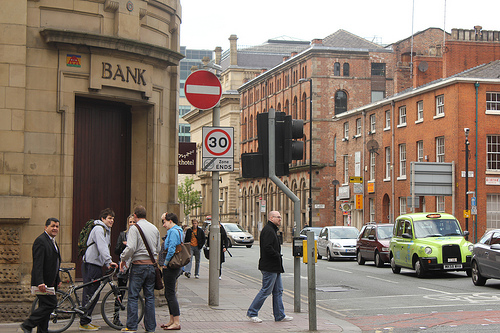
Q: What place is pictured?
A: It is a street.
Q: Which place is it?
A: It is a street.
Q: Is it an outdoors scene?
A: Yes, it is outdoors.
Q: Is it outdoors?
A: Yes, it is outdoors.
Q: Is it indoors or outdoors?
A: It is outdoors.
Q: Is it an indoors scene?
A: No, it is outdoors.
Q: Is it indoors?
A: No, it is outdoors.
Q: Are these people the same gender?
A: No, they are both male and female.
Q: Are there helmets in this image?
A: No, there are no helmets.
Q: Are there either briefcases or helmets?
A: No, there are no helmets or briefcases.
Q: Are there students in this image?
A: No, there are no students.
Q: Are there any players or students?
A: No, there are no students or players.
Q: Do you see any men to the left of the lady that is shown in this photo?
A: Yes, there is a man to the left of the lady.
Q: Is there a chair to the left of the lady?
A: No, there is a man to the left of the lady.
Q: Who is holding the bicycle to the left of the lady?
A: The man is holding the bicycle.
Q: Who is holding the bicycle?
A: The man is holding the bicycle.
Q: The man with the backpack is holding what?
A: The man is holding the bicycle.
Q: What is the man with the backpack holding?
A: The man is holding the bicycle.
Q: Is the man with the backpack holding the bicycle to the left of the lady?
A: Yes, the man is holding the bicycle.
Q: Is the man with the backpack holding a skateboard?
A: No, the man is holding the bicycle.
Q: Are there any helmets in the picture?
A: No, there are no helmets.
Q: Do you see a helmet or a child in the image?
A: No, there are no helmets or children.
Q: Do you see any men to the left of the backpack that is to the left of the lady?
A: Yes, there is a man to the left of the backpack.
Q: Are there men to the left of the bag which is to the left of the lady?
A: Yes, there is a man to the left of the backpack.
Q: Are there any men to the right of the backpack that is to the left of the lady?
A: No, the man is to the left of the backpack.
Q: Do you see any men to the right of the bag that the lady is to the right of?
A: No, the man is to the left of the backpack.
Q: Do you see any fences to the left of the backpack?
A: No, there is a man to the left of the backpack.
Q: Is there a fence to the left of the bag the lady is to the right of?
A: No, there is a man to the left of the backpack.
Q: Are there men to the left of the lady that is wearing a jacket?
A: Yes, there is a man to the left of the lady.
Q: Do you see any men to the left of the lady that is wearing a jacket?
A: Yes, there is a man to the left of the lady.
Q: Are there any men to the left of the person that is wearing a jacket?
A: Yes, there is a man to the left of the lady.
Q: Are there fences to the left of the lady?
A: No, there is a man to the left of the lady.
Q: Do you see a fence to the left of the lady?
A: No, there is a man to the left of the lady.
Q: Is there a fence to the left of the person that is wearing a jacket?
A: No, there is a man to the left of the lady.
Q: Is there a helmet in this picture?
A: No, there are no helmets.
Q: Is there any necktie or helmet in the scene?
A: No, there are no helmets or ties.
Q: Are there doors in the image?
A: Yes, there is a door.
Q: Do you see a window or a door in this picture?
A: Yes, there is a door.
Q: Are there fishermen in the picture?
A: No, there are no fishermen.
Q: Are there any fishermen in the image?
A: No, there are no fishermen.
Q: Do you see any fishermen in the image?
A: No, there are no fishermen.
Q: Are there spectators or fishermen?
A: No, there are no fishermen or spectators.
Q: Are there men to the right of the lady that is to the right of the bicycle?
A: Yes, there is a man to the right of the lady.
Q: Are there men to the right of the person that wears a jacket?
A: Yes, there is a man to the right of the lady.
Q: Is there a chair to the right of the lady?
A: No, there is a man to the right of the lady.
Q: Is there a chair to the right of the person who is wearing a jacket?
A: No, there is a man to the right of the lady.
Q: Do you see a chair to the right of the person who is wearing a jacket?
A: No, there is a man to the right of the lady.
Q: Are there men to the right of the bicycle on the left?
A: Yes, there is a man to the right of the bicycle.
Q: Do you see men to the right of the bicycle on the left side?
A: Yes, there is a man to the right of the bicycle.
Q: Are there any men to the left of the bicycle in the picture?
A: No, the man is to the right of the bicycle.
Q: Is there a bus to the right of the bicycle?
A: No, there is a man to the right of the bicycle.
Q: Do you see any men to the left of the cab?
A: Yes, there is a man to the left of the cab.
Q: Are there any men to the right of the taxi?
A: No, the man is to the left of the taxi.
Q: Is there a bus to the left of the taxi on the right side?
A: No, there is a man to the left of the cab.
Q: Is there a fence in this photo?
A: No, there are no fences.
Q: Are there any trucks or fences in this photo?
A: No, there are no fences or trucks.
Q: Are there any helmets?
A: No, there are no helmets.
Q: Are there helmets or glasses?
A: No, there are no helmets or glasses.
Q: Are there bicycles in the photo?
A: Yes, there is a bicycle.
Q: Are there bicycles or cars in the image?
A: Yes, there is a bicycle.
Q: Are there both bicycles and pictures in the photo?
A: No, there is a bicycle but no pictures.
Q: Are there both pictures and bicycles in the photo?
A: No, there is a bicycle but no pictures.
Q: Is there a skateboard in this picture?
A: No, there are no skateboards.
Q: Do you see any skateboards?
A: No, there are no skateboards.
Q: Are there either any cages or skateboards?
A: No, there are no skateboards or cages.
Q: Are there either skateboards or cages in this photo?
A: No, there are no skateboards or cages.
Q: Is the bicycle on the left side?
A: Yes, the bicycle is on the left of the image.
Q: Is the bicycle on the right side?
A: No, the bicycle is on the left of the image.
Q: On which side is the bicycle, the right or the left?
A: The bicycle is on the left of the image.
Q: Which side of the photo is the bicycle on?
A: The bicycle is on the left of the image.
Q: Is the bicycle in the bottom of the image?
A: Yes, the bicycle is in the bottom of the image.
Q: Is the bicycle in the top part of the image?
A: No, the bicycle is in the bottom of the image.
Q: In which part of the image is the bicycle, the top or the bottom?
A: The bicycle is in the bottom of the image.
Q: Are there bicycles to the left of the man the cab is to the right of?
A: Yes, there is a bicycle to the left of the man.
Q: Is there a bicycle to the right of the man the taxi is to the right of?
A: No, the bicycle is to the left of the man.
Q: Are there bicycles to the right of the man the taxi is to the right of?
A: No, the bicycle is to the left of the man.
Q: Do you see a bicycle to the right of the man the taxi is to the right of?
A: No, the bicycle is to the left of the man.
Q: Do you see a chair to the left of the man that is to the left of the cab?
A: No, there is a bicycle to the left of the man.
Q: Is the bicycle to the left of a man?
A: Yes, the bicycle is to the left of a man.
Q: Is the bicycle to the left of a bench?
A: No, the bicycle is to the left of a man.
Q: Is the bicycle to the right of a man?
A: No, the bicycle is to the left of a man.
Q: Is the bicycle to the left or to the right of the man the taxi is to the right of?
A: The bicycle is to the left of the man.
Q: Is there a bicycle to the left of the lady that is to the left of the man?
A: Yes, there is a bicycle to the left of the lady.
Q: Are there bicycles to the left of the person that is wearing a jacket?
A: Yes, there is a bicycle to the left of the lady.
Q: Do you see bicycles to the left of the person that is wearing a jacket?
A: Yes, there is a bicycle to the left of the lady.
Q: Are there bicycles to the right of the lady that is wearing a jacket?
A: No, the bicycle is to the left of the lady.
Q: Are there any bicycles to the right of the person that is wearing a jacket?
A: No, the bicycle is to the left of the lady.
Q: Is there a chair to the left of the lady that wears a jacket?
A: No, there is a bicycle to the left of the lady.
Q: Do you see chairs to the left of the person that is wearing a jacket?
A: No, there is a bicycle to the left of the lady.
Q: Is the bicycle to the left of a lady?
A: Yes, the bicycle is to the left of a lady.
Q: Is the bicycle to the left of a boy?
A: No, the bicycle is to the left of a lady.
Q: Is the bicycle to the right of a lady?
A: No, the bicycle is to the left of a lady.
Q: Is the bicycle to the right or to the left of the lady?
A: The bicycle is to the left of the lady.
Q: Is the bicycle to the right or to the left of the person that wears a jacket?
A: The bicycle is to the left of the lady.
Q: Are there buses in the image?
A: No, there are no buses.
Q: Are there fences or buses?
A: No, there are no buses or fences.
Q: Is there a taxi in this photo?
A: Yes, there is a taxi.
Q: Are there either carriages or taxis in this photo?
A: Yes, there is a taxi.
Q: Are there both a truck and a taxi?
A: No, there is a taxi but no trucks.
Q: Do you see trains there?
A: No, there are no trains.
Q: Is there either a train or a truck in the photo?
A: No, there are no trains or trucks.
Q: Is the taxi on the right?
A: Yes, the taxi is on the right of the image.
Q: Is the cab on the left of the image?
A: No, the cab is on the right of the image.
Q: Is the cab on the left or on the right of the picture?
A: The cab is on the right of the image.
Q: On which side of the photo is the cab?
A: The cab is on the right of the image.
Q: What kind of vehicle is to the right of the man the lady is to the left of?
A: The vehicle is a taxi.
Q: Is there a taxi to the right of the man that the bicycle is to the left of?
A: Yes, there is a taxi to the right of the man.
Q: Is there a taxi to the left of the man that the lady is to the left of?
A: No, the taxi is to the right of the man.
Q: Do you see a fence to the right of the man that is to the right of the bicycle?
A: No, there is a taxi to the right of the man.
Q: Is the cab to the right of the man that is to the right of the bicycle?
A: Yes, the cab is to the right of the man.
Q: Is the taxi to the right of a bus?
A: No, the taxi is to the right of the man.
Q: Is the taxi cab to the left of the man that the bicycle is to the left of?
A: No, the taxi cab is to the right of the man.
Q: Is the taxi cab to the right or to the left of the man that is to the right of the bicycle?
A: The taxi cab is to the right of the man.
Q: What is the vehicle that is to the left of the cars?
A: The vehicle is a taxi.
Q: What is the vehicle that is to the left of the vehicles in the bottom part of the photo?
A: The vehicle is a taxi.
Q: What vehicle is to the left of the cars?
A: The vehicle is a taxi.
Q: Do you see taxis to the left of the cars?
A: Yes, there is a taxi to the left of the cars.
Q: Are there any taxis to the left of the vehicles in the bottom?
A: Yes, there is a taxi to the left of the cars.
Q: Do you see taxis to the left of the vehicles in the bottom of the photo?
A: Yes, there is a taxi to the left of the cars.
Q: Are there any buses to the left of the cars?
A: No, there is a taxi to the left of the cars.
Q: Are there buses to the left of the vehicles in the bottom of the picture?
A: No, there is a taxi to the left of the cars.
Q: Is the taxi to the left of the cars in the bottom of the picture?
A: Yes, the taxi is to the left of the cars.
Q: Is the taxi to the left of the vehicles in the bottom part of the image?
A: Yes, the taxi is to the left of the cars.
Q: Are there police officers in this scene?
A: No, there are no police officers.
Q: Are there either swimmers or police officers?
A: No, there are no police officers or swimmers.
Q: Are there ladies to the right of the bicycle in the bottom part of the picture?
A: Yes, there is a lady to the right of the bicycle.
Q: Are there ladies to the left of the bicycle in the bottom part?
A: No, the lady is to the right of the bicycle.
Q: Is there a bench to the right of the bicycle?
A: No, there is a lady to the right of the bicycle.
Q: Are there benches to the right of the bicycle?
A: No, there is a lady to the right of the bicycle.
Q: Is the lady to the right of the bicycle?
A: Yes, the lady is to the right of the bicycle.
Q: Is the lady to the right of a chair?
A: No, the lady is to the right of the bicycle.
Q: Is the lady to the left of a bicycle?
A: No, the lady is to the right of a bicycle.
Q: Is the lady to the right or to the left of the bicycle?
A: The lady is to the right of the bicycle.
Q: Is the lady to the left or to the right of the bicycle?
A: The lady is to the right of the bicycle.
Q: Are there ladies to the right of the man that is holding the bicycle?
A: Yes, there is a lady to the right of the man.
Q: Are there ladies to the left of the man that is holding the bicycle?
A: No, the lady is to the right of the man.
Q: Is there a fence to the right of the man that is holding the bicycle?
A: No, there is a lady to the right of the man.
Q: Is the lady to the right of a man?
A: Yes, the lady is to the right of a man.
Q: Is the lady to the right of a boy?
A: No, the lady is to the right of a man.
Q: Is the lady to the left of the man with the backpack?
A: No, the lady is to the right of the man.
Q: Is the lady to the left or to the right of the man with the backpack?
A: The lady is to the right of the man.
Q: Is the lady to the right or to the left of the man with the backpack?
A: The lady is to the right of the man.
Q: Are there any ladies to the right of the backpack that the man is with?
A: Yes, there is a lady to the right of the backpack.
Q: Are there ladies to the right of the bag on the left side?
A: Yes, there is a lady to the right of the backpack.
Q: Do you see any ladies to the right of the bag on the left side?
A: Yes, there is a lady to the right of the backpack.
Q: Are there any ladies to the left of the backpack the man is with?
A: No, the lady is to the right of the backpack.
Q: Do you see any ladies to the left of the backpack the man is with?
A: No, the lady is to the right of the backpack.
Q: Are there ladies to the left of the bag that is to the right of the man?
A: No, the lady is to the right of the backpack.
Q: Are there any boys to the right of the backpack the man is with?
A: No, there is a lady to the right of the backpack.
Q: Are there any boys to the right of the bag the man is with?
A: No, there is a lady to the right of the backpack.